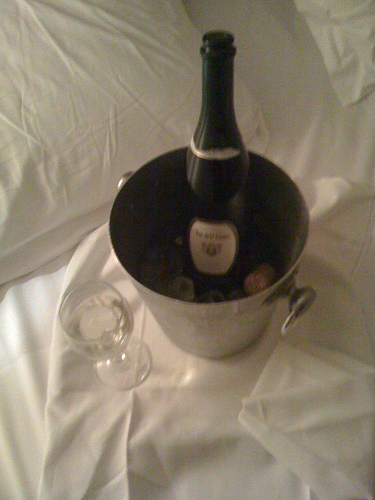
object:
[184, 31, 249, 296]
bottle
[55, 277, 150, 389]
glass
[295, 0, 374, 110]
sheet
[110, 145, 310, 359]
bucket